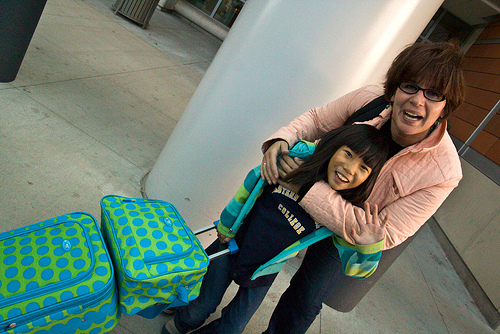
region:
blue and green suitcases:
[35, 201, 194, 331]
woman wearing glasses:
[372, 45, 462, 122]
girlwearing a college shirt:
[197, 195, 327, 287]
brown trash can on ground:
[75, 3, 171, 49]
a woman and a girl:
[245, 78, 480, 262]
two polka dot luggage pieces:
[14, 213, 220, 330]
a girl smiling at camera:
[293, 135, 392, 230]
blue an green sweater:
[189, 140, 380, 303]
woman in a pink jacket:
[348, 68, 458, 263]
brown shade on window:
[444, 28, 493, 180]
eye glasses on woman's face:
[392, 81, 452, 102]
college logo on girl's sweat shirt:
[264, 179, 329, 245]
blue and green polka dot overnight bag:
[98, 190, 208, 321]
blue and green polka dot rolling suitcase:
[1, 217, 121, 332]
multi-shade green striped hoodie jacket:
[212, 139, 389, 296]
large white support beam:
[133, 0, 440, 235]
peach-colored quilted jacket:
[260, 79, 463, 249]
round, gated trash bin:
[104, 0, 166, 32]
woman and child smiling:
[206, 37, 463, 332]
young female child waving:
[189, 119, 392, 333]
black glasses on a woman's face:
[392, 77, 450, 106]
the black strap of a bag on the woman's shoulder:
[348, 82, 385, 118]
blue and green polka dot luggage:
[11, 170, 201, 325]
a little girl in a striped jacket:
[215, 130, 407, 306]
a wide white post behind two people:
[245, 2, 382, 92]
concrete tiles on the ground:
[58, 17, 153, 159]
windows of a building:
[212, 1, 235, 30]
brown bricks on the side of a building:
[471, 60, 498, 137]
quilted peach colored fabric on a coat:
[397, 153, 429, 193]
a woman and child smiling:
[210, 34, 485, 323]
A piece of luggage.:
[0, 193, 236, 332]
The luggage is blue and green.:
[3, 188, 248, 328]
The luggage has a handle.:
[179, 213, 245, 276]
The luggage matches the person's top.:
[3, 139, 386, 332]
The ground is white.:
[13, 122, 78, 200]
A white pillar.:
[138, 0, 453, 224]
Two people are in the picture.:
[189, 40, 474, 332]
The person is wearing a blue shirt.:
[226, 141, 332, 285]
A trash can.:
[101, 0, 168, 37]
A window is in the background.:
[156, 0, 258, 45]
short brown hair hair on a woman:
[380, 37, 475, 134]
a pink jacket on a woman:
[266, 72, 471, 252]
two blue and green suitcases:
[15, 195, 240, 330]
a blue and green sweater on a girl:
[215, 141, 372, 277]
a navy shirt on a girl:
[230, 180, 325, 265]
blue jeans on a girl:
[170, 255, 272, 330]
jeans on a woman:
[255, 231, 362, 327]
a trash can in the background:
[110, 0, 160, 35]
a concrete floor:
[0, 20, 490, 330]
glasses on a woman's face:
[392, 71, 448, 103]